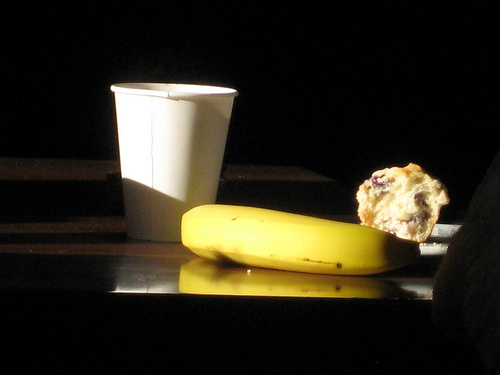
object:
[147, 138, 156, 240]
seam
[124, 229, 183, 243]
base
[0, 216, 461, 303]
table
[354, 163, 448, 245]
food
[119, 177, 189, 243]
shadow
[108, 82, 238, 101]
mouth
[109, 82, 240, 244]
cup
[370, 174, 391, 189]
fruit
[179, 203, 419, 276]
banana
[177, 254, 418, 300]
reflection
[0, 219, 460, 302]
surface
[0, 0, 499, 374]
background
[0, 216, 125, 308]
shadow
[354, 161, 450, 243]
snack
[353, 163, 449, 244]
muffin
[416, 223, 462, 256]
plate